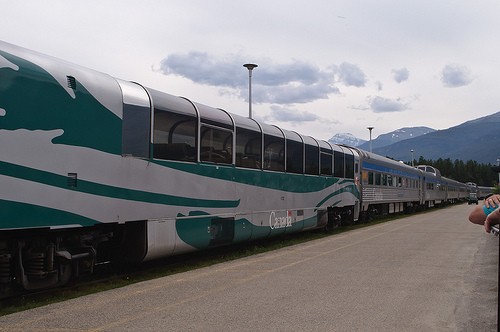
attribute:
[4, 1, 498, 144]
sky — clear, blue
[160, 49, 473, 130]
clouds — white, puffy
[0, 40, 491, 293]
train — large, green, silver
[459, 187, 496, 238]
passengers — diembodied, leaning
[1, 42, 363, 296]
car — green, designed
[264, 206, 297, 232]
text — white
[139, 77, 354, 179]
windows — tinted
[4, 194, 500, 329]
platform — gravel road?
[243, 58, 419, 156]
lights — black, metal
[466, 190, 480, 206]
cart — small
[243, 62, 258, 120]
pole — metal, tall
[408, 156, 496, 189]
trees — green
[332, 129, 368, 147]
mountain top — covered in snow